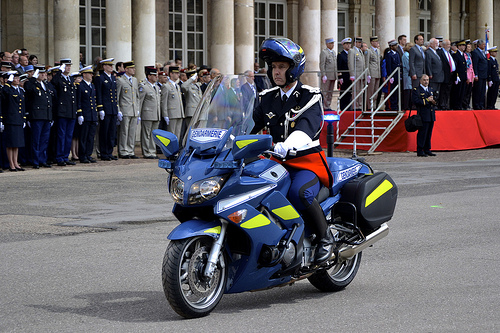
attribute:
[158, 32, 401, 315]
motorcycle — soldier, policeman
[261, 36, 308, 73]
man — helmet 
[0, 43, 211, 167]
military people —  standing 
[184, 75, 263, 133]
motorcycle — windshield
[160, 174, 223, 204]
motorcycle — headlights 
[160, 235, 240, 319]
motorcycle — tire 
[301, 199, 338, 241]
man — boot 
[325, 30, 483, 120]
people — standing 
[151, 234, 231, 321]
wheels — black 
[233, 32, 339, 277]
person — uniform 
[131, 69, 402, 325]
motorcycle — blue 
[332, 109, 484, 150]
stage — RED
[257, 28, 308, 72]
helmet — blue 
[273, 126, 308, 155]
gloves — white 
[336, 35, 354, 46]
hat — white 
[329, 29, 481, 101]
people — group 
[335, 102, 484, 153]
platform — red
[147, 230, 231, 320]
motorcycle — front wheel 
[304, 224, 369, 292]
motorcycle — back wheel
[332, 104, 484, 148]
stand — red band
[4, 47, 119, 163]
military — white, blue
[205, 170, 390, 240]
motorcycle — yellow strip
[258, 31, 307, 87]
helmet — BLUE, BLACK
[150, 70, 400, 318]
motorcycle — NEON GREEN, BLUE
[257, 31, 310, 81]
helmet — LARGE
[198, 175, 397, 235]
stripes — GREEN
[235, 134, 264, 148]
stripes — GREEN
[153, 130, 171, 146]
stripes — GREEN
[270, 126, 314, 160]
gloves — WHITE